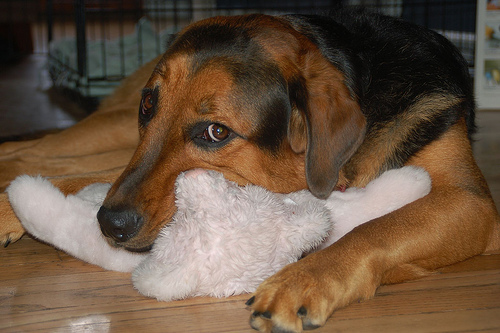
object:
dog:
[0, 9, 499, 331]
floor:
[3, 108, 499, 329]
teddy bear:
[6, 161, 431, 301]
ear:
[290, 71, 368, 199]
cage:
[43, 4, 475, 107]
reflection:
[61, 312, 116, 332]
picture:
[474, 2, 500, 114]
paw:
[245, 246, 366, 330]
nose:
[97, 206, 133, 241]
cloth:
[52, 21, 173, 96]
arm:
[7, 173, 140, 272]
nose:
[181, 166, 210, 183]